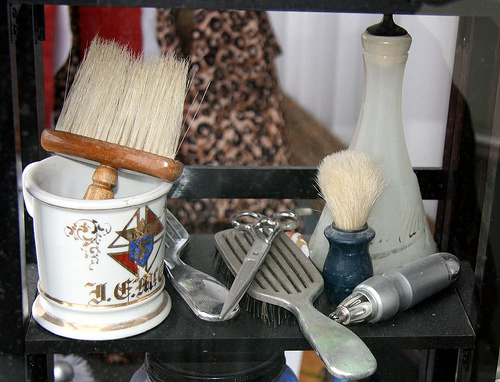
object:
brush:
[214, 217, 378, 380]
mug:
[21, 154, 173, 343]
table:
[11, 230, 478, 380]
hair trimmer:
[327, 252, 464, 327]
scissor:
[218, 211, 299, 321]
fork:
[165, 210, 238, 322]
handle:
[292, 299, 378, 382]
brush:
[312, 148, 388, 304]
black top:
[367, 9, 409, 38]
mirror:
[38, 4, 457, 170]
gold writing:
[84, 281, 104, 308]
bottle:
[308, 31, 439, 284]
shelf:
[23, 232, 477, 356]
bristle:
[276, 307, 280, 327]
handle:
[80, 163, 118, 199]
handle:
[320, 228, 376, 300]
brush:
[40, 33, 211, 200]